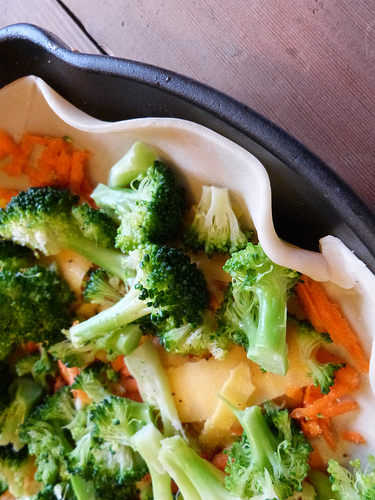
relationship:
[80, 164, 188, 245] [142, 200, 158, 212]
broccoli spear green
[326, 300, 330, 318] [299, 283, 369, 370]
small slice carrot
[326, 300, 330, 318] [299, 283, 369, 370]
small slice of carrot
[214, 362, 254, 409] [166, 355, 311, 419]
slice of cheese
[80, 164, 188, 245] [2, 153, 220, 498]
broccoli in salad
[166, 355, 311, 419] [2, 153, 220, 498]
cheese in salad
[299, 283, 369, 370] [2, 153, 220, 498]
carrot in salad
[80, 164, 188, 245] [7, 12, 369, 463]
broccoli on dish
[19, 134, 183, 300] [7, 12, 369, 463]
vegetables on dish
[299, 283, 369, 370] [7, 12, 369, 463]
carrot on dish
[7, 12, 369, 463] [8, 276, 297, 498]
dish with food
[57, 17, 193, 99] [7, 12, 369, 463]
pan with dish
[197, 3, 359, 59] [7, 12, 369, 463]
table under dish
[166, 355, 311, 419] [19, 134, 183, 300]
cheese on vegetables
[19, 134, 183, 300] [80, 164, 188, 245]
vegetables and broccoli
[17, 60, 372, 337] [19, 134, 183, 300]
dish with vegetables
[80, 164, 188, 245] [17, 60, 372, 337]
broccoli in dish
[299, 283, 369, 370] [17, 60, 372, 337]
carrot in dish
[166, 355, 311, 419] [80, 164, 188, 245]
cheese and broccoli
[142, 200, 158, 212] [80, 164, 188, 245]
green cutup broccoli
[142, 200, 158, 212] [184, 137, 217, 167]
green and white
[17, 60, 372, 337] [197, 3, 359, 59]
dish on table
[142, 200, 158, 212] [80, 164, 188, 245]
green bright broccoli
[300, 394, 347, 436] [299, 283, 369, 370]
shreds of carrot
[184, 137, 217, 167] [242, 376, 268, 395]
white uncooked dough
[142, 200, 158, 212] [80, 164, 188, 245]
green dark broccoli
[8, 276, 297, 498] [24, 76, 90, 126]
food in crust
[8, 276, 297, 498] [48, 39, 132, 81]
food in skillet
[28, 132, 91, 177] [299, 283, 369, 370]
shredded pile of carrot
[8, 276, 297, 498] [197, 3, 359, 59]
food on table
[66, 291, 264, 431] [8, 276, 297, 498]
mixture of food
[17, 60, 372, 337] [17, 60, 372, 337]
dish inside dish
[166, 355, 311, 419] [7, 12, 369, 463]
cheese inside dish